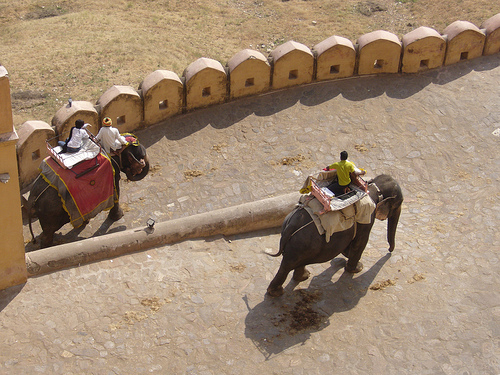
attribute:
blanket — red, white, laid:
[77, 167, 132, 209]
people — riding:
[73, 115, 117, 146]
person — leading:
[97, 115, 131, 146]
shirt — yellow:
[328, 163, 359, 186]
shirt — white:
[70, 136, 107, 161]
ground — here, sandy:
[316, 101, 494, 161]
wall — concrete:
[225, 49, 377, 77]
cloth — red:
[57, 173, 96, 200]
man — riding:
[296, 138, 407, 241]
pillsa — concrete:
[217, 35, 269, 97]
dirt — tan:
[188, 124, 281, 189]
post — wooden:
[125, 208, 257, 257]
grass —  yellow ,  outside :
[135, 19, 246, 67]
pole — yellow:
[1, 138, 42, 270]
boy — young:
[61, 118, 90, 136]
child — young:
[63, 119, 105, 169]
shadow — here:
[36, 233, 100, 245]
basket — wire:
[46, 153, 94, 172]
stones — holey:
[164, 77, 259, 101]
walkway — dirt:
[250, 104, 458, 177]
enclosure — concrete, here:
[180, 51, 499, 74]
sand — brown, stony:
[122, 279, 288, 357]